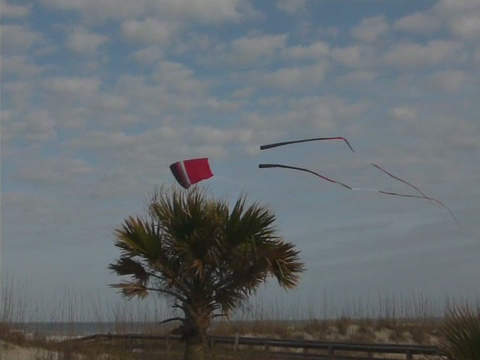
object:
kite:
[168, 158, 216, 190]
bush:
[427, 292, 480, 360]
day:
[0, 0, 480, 323]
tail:
[258, 137, 467, 235]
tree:
[106, 180, 307, 359]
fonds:
[104, 181, 309, 360]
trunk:
[182, 310, 213, 359]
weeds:
[0, 278, 480, 360]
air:
[0, 0, 480, 319]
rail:
[209, 333, 480, 360]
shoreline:
[0, 317, 480, 334]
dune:
[213, 318, 480, 360]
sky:
[0, 0, 480, 326]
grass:
[0, 269, 480, 360]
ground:
[0, 319, 480, 360]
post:
[57, 333, 188, 345]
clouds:
[0, 0, 480, 322]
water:
[0, 319, 129, 336]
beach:
[0, 288, 480, 360]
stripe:
[178, 161, 191, 186]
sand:
[0, 337, 64, 360]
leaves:
[105, 177, 308, 325]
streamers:
[254, 135, 465, 228]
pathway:
[236, 321, 479, 359]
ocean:
[0, 311, 480, 337]